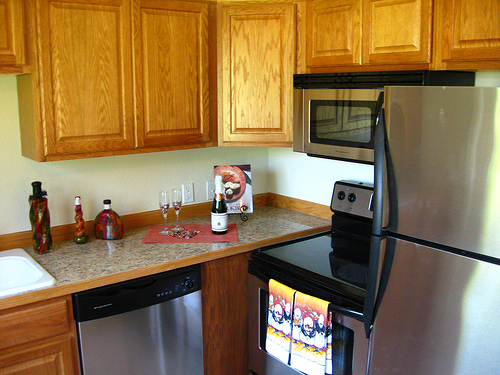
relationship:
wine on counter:
[210, 167, 231, 236] [26, 198, 337, 302]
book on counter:
[211, 161, 256, 217] [26, 198, 337, 302]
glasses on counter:
[157, 187, 186, 239] [26, 198, 337, 302]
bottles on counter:
[72, 195, 90, 245] [26, 198, 337, 302]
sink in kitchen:
[1, 245, 60, 309] [2, 3, 496, 371]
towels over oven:
[264, 274, 339, 374] [240, 175, 367, 369]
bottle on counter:
[210, 167, 231, 236] [26, 198, 337, 302]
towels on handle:
[264, 274, 339, 374] [247, 262, 364, 332]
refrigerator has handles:
[371, 77, 498, 372] [360, 106, 391, 340]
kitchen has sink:
[2, 3, 496, 371] [1, 245, 60, 309]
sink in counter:
[1, 245, 60, 309] [26, 198, 337, 302]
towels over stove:
[264, 274, 339, 374] [240, 175, 367, 369]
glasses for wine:
[157, 187, 186, 239] [210, 167, 231, 236]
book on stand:
[211, 161, 256, 217] [231, 206, 255, 222]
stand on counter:
[231, 206, 255, 222] [26, 198, 337, 302]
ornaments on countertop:
[25, 178, 125, 255] [26, 198, 337, 302]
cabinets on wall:
[2, 2, 499, 166] [2, 3, 498, 183]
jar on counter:
[94, 199, 127, 244] [26, 198, 337, 302]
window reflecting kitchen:
[308, 99, 378, 151] [2, 3, 496, 371]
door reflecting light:
[308, 99, 378, 151] [316, 109, 371, 138]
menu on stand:
[211, 161, 256, 217] [231, 206, 255, 222]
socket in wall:
[182, 182, 197, 206] [2, 3, 498, 183]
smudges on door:
[396, 177, 450, 274] [377, 83, 498, 354]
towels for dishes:
[264, 274, 339, 374] [157, 187, 186, 239]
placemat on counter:
[139, 218, 243, 245] [26, 198, 337, 302]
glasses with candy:
[157, 187, 186, 239] [160, 201, 186, 215]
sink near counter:
[1, 245, 60, 309] [26, 198, 337, 302]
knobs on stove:
[330, 191, 360, 210] [240, 175, 367, 369]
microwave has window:
[288, 71, 392, 166] [308, 99, 378, 151]